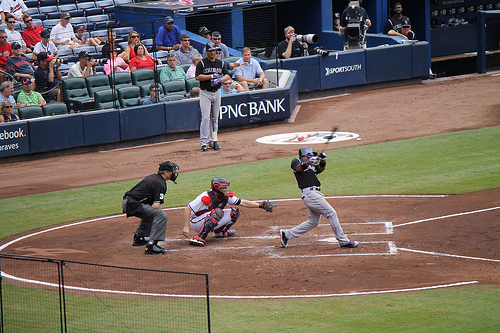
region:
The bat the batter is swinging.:
[316, 127, 335, 167]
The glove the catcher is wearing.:
[255, 201, 273, 210]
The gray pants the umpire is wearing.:
[121, 196, 172, 246]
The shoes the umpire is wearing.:
[135, 236, 167, 254]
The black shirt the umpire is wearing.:
[126, 169, 166, 201]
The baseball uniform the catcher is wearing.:
[191, 187, 238, 235]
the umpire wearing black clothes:
[114, 153, 182, 259]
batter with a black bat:
[262, 117, 368, 257]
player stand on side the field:
[183, 41, 232, 155]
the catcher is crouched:
[174, 173, 282, 244]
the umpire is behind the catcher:
[108, 146, 279, 261]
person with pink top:
[99, 46, 133, 83]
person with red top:
[125, 40, 157, 71]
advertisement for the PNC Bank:
[217, 95, 293, 122]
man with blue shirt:
[230, 44, 274, 95]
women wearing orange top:
[121, 26, 159, 77]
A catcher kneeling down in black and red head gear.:
[182, 177, 274, 245]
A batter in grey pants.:
[278, 144, 358, 248]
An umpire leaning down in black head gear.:
[120, 161, 179, 254]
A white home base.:
[317, 236, 339, 244]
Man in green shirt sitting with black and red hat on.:
[15, 78, 47, 107]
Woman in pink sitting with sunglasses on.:
[101, 47, 130, 74]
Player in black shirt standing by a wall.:
[194, 43, 228, 152]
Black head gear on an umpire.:
[158, 160, 179, 182]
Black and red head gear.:
[209, 176, 231, 199]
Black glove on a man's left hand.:
[260, 197, 277, 212]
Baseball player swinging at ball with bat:
[278, 123, 360, 253]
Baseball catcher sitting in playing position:
[178, 174, 277, 244]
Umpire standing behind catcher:
[120, 160, 185, 255]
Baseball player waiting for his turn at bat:
[193, 40, 249, 150]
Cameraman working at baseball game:
[273, 23, 320, 58]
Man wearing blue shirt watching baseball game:
[152, 10, 182, 51]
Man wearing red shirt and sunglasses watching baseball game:
[21, 11, 48, 48]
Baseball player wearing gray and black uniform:
[194, 40, 232, 150]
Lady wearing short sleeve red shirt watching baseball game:
[126, 41, 157, 71]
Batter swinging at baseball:
[274, 119, 362, 254]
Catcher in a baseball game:
[187, 171, 264, 243]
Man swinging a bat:
[281, 126, 366, 258]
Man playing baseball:
[281, 143, 373, 260]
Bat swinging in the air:
[306, 118, 342, 171]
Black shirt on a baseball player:
[192, 57, 232, 94]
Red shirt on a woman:
[133, 52, 158, 69]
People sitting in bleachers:
[5, 12, 275, 113]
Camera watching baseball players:
[334, 8, 368, 42]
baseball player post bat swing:
[280, 120, 355, 249]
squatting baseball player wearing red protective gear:
[183, 172, 277, 246]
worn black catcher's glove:
[258, 197, 277, 212]